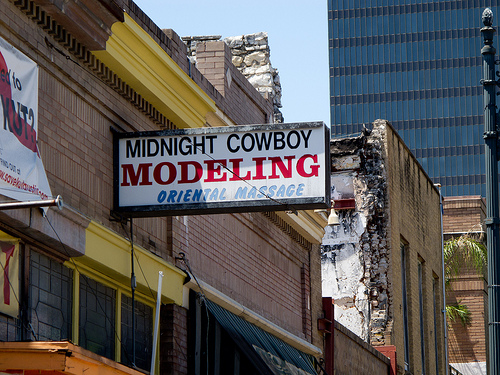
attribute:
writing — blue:
[144, 185, 328, 220]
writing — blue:
[147, 180, 308, 216]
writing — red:
[122, 156, 377, 191]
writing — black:
[126, 133, 313, 149]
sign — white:
[116, 120, 376, 210]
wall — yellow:
[86, 22, 222, 172]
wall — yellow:
[66, 223, 204, 321]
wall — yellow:
[264, 180, 362, 247]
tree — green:
[426, 224, 495, 288]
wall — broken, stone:
[321, 155, 408, 367]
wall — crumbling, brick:
[313, 145, 422, 346]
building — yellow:
[19, 62, 333, 372]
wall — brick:
[6, 54, 315, 315]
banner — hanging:
[0, 70, 76, 218]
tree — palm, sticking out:
[432, 234, 497, 329]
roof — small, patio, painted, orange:
[24, 325, 142, 371]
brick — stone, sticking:
[182, 32, 288, 113]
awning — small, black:
[206, 292, 348, 362]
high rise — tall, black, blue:
[334, 44, 486, 270]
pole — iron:
[463, 58, 498, 363]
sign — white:
[101, 126, 323, 217]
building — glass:
[324, 50, 490, 200]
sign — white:
[115, 99, 377, 227]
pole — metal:
[471, 54, 498, 247]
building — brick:
[37, 125, 303, 332]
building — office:
[329, 43, 479, 248]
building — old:
[319, 119, 444, 373]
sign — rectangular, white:
[115, 119, 335, 219]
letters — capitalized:
[120, 150, 321, 186]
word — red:
[120, 150, 321, 190]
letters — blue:
[152, 186, 299, 202]